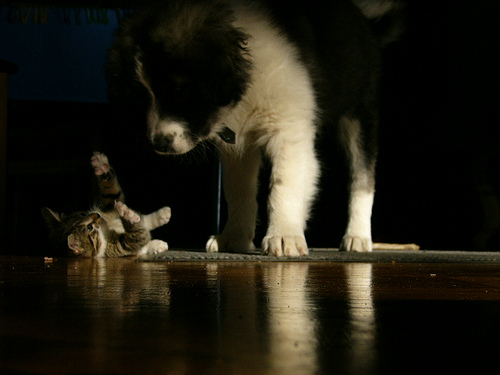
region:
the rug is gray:
[246, 240, 253, 257]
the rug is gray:
[186, 231, 201, 289]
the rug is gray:
[191, 252, 200, 262]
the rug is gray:
[173, 242, 195, 250]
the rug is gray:
[197, 246, 207, 258]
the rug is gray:
[170, 242, 180, 266]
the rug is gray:
[176, 241, 196, 275]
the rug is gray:
[195, 242, 227, 290]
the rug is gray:
[200, 250, 211, 265]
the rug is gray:
[193, 246, 198, 252]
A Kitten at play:
[41, 142, 175, 264]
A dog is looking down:
[102, 11, 411, 261]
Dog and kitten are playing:
[43, 5, 413, 275]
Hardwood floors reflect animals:
[4, 258, 499, 373]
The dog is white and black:
[101, 15, 408, 270]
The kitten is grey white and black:
[43, 151, 173, 276]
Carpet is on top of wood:
[147, 246, 498, 267]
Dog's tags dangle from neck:
[211, 123, 245, 150]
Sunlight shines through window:
[32, 193, 497, 305]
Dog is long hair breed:
[109, 4, 414, 269]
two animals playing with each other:
[30, 3, 459, 277]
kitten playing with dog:
[38, 136, 177, 273]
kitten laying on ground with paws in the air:
[42, 134, 179, 276]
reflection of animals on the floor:
[72, 265, 387, 361]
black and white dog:
[142, 16, 399, 270]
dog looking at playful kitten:
[132, 13, 249, 179]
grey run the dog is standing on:
[134, 240, 499, 267]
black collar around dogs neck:
[212, 116, 242, 152]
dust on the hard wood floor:
[373, 254, 485, 301]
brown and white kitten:
[47, 151, 183, 268]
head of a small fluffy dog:
[122, 26, 229, 167]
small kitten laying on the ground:
[56, 158, 173, 271]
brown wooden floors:
[96, 265, 389, 354]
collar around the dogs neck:
[205, 113, 246, 161]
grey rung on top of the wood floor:
[189, 230, 424, 262]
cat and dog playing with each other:
[43, 7, 370, 269]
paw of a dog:
[259, 221, 307, 268]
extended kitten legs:
[69, 153, 147, 261]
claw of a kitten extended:
[106, 194, 128, 207]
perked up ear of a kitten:
[41, 193, 80, 233]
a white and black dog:
[125, 12, 446, 274]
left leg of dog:
[258, 140, 322, 267]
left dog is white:
[260, 155, 324, 263]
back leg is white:
[335, 187, 379, 255]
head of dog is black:
[100, 7, 261, 175]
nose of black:
[138, 127, 188, 159]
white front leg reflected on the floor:
[247, 260, 324, 374]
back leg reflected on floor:
[335, 264, 383, 348]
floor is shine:
[10, 265, 498, 373]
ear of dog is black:
[194, 24, 251, 115]